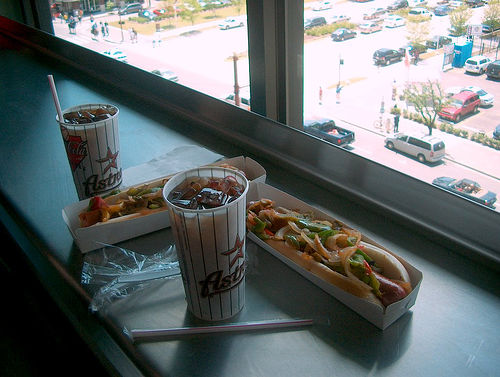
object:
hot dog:
[247, 189, 420, 317]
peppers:
[318, 222, 331, 239]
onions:
[312, 234, 332, 259]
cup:
[53, 103, 133, 205]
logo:
[81, 150, 125, 192]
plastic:
[76, 240, 192, 317]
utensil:
[116, 265, 181, 288]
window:
[21, 2, 499, 209]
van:
[384, 130, 448, 162]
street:
[300, 111, 499, 213]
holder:
[242, 194, 423, 330]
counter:
[1, 44, 499, 370]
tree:
[403, 77, 444, 137]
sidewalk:
[314, 82, 499, 180]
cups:
[163, 164, 248, 322]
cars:
[425, 176, 499, 206]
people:
[392, 105, 405, 136]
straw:
[123, 316, 325, 337]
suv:
[439, 90, 480, 123]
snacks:
[41, 73, 425, 334]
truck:
[303, 117, 356, 147]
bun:
[247, 193, 411, 311]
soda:
[160, 165, 248, 220]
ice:
[194, 186, 229, 204]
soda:
[61, 105, 110, 127]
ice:
[76, 113, 97, 122]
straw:
[44, 70, 72, 131]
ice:
[217, 179, 236, 194]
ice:
[96, 105, 115, 117]